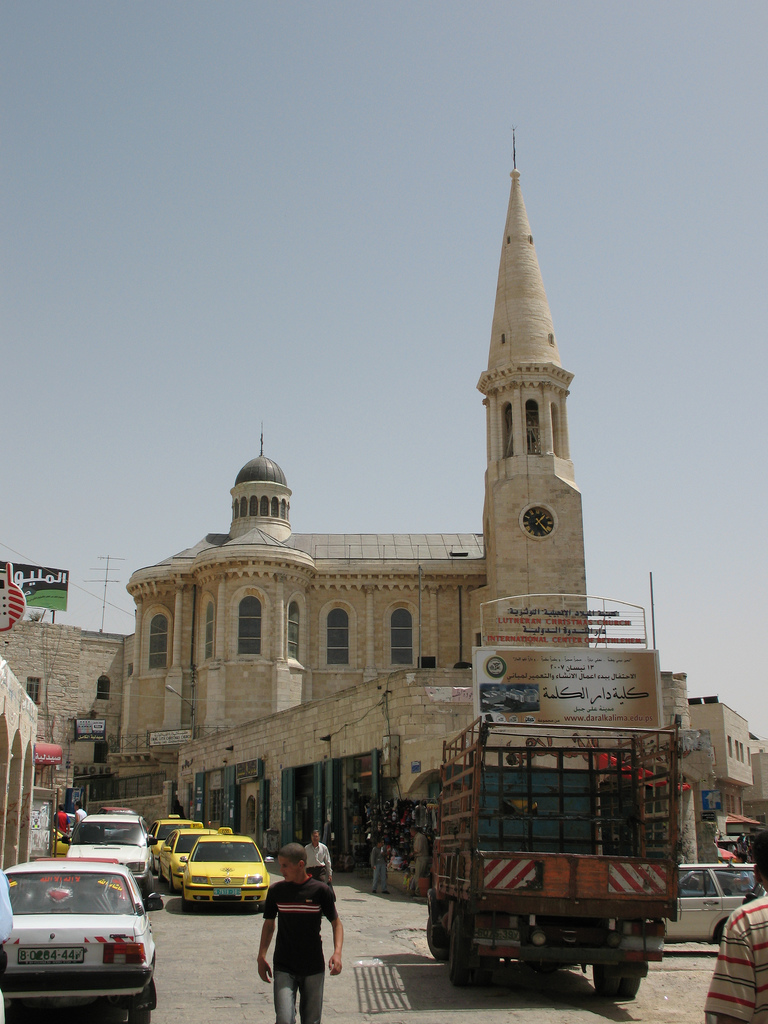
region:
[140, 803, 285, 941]
Line of yellow taxi cabs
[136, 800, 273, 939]
Line of yellow cars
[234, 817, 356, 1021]
Man walking in street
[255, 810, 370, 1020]
two men walking on the road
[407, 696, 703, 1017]
Stake body truck on road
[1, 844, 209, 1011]
White car parked on curb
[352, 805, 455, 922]
Men standing by the side of road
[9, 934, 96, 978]
License plate on white car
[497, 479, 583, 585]
a clock built into a stone wall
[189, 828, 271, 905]
a yellow taxi cab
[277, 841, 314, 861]
a boy with black hair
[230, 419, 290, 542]
a dome on the top of a building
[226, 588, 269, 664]
a window with an arch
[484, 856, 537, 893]
red and white reflective decal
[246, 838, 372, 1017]
a boy walking down the street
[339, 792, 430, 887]
items on display outside a store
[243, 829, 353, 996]
A man wearing a black shirt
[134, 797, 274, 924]
Yellow cars in a row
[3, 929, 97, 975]
A rectangular license plate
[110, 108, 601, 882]
A large light brown building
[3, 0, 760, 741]
The sky is slightly overcast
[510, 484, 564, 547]
A round black clock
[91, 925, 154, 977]
A red rear light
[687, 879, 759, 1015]
Stripes on a shirt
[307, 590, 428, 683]
Two windows on a building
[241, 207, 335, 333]
the sky is clear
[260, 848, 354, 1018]
a man walking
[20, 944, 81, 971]
license plate on the car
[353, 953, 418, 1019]
a shadow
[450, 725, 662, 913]
a truck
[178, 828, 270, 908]
a yellow car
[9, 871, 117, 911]
windshield of the car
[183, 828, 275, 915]
the car is yellow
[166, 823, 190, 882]
the car is yellow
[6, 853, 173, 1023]
the car is white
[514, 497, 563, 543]
a clock on a tower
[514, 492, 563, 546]
the clock is black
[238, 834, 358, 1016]
man walking on the street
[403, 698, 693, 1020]
the truck is orange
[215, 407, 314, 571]
a dome on a church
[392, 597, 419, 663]
A window on a building.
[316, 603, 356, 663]
A window on a building.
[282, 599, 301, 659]
A window on a building.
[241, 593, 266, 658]
A window on a building.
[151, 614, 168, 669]
A window on a building.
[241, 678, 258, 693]
A brick in a wall.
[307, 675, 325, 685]
A brick in a wall.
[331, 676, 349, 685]
A brick in a wall.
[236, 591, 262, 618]
glass window on the building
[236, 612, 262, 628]
glass window on the building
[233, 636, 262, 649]
glass window on the building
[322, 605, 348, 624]
glass window on the building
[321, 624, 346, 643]
glass window on the building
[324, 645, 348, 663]
glass window on the building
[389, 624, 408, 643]
glass window on the building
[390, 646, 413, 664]
glass window on the building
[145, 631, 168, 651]
glass window on the building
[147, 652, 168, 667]
glass window on the building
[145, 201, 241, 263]
clear blue sky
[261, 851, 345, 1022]
a man standing